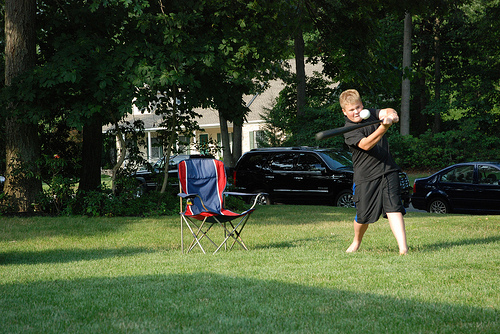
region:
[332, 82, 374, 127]
head of a person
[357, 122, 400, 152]
arm of a person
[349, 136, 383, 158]
elbow of a person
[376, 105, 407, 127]
hand of a person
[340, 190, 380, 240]
leg of a person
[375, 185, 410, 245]
leg of a person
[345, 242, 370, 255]
feet of a person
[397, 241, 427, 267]
feet of a person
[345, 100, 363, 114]
eye of a person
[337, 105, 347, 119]
ear of a person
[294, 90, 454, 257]
fat kid playing baseball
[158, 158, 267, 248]
a blue red and white folding chair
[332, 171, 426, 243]
a pair of black mesh shorts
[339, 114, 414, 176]
a black t-shirt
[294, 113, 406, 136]
a black baseball bat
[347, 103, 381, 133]
a whtie baseball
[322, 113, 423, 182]
a large black t-shirt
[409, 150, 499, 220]
a blue four door sedan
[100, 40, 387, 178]
a large white house in the background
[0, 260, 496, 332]
a house casting a shadow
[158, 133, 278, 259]
this is a chair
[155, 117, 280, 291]
a foldable chair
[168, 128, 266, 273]
the chair is foldable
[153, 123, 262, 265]
the chair is empty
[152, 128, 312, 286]
the chair is blue and red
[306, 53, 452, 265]
he is dressed in black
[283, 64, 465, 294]
he is going to hit the ball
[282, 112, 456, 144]
a black baseball bat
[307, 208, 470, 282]
he is not wearing shoes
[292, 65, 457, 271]
he is playing baseball in a park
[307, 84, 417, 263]
A boy is swinging a bat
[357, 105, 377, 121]
A white ball in the air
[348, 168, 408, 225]
Boy wearing black shorts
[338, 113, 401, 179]
Boy wearing a black shirt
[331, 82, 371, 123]
Boy has blonde hair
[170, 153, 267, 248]
Blue and red camping chair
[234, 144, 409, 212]
A black van is parked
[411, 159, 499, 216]
A blue car is parked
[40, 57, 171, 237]
Tall trees in the background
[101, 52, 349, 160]
A house in the background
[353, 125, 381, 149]
arm of a person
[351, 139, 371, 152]
elbow of a person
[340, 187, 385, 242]
leg of a person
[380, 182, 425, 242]
leg of a person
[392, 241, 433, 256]
feet of a person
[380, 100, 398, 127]
hand of a person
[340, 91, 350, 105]
hair of a person